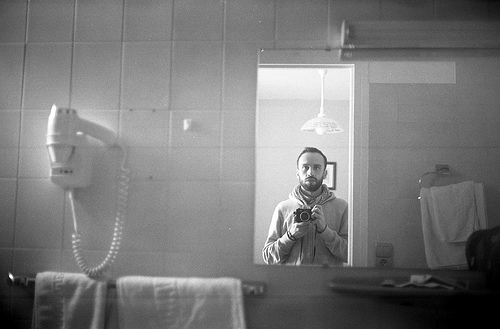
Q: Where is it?
A: This is at the bathroom.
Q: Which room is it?
A: It is a bathroom.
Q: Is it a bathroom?
A: Yes, it is a bathroom.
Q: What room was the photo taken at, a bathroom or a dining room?
A: It was taken at a bathroom.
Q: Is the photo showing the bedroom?
A: No, the picture is showing the bathroom.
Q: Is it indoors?
A: Yes, it is indoors.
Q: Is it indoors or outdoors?
A: It is indoors.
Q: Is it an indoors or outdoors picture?
A: It is indoors.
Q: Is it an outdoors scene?
A: No, it is indoors.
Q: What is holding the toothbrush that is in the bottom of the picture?
A: The bathroom is holding the toothbrush.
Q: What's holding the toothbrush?
A: The bathroom is holding the toothbrush.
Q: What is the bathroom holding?
A: The bathroom is holding the toothbrush.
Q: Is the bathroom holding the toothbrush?
A: Yes, the bathroom is holding the toothbrush.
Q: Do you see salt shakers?
A: No, there are no salt shakers.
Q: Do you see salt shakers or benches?
A: No, there are no salt shakers or benches.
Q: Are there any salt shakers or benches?
A: No, there are no salt shakers or benches.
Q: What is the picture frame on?
A: The picture frame is on the wall.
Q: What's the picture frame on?
A: The picture frame is on the wall.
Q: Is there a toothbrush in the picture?
A: Yes, there is a toothbrush.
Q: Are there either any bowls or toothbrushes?
A: Yes, there is a toothbrush.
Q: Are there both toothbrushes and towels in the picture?
A: Yes, there are both a toothbrush and a towel.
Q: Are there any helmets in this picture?
A: No, there are no helmets.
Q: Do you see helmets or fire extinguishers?
A: No, there are no helmets or fire extinguishers.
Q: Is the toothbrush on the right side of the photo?
A: Yes, the toothbrush is on the right of the image.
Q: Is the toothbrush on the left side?
A: No, the toothbrush is on the right of the image.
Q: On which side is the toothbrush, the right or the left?
A: The toothbrush is on the right of the image.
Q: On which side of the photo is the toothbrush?
A: The toothbrush is on the right of the image.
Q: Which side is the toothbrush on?
A: The toothbrush is on the right of the image.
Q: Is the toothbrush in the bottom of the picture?
A: Yes, the toothbrush is in the bottom of the image.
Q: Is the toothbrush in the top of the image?
A: No, the toothbrush is in the bottom of the image.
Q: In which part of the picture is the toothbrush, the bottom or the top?
A: The toothbrush is in the bottom of the image.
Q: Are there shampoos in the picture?
A: No, there are no shampoos.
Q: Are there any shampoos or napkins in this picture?
A: No, there are no shampoos or napkins.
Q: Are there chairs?
A: No, there are no chairs.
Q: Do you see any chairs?
A: No, there are no chairs.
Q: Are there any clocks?
A: No, there are no clocks.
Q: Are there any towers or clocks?
A: No, there are no clocks or towers.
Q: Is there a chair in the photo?
A: No, there are no chairs.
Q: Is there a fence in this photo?
A: No, there are no fences.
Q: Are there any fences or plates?
A: No, there are no fences or plates.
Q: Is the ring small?
A: Yes, the ring is small.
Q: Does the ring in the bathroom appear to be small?
A: Yes, the ring is small.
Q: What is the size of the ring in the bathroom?
A: The ring is small.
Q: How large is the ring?
A: The ring is small.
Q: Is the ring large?
A: No, the ring is small.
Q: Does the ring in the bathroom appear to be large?
A: No, the ring is small.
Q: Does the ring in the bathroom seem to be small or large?
A: The ring is small.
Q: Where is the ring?
A: The ring is in the bathroom.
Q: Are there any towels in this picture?
A: Yes, there is a towel.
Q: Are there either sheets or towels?
A: Yes, there is a towel.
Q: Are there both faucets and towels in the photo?
A: No, there is a towel but no faucets.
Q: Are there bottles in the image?
A: No, there are no bottles.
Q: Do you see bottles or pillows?
A: No, there are no bottles or pillows.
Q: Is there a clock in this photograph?
A: No, there are no clocks.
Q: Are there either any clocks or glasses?
A: No, there are no clocks or glasses.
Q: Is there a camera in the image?
A: Yes, there is a camera.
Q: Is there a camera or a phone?
A: Yes, there is a camera.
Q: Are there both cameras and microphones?
A: No, there is a camera but no microphones.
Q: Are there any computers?
A: No, there are no computers.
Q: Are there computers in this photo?
A: No, there are no computers.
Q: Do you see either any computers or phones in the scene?
A: No, there are no computers or phones.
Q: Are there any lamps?
A: Yes, there is a lamp.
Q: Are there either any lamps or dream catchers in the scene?
A: Yes, there is a lamp.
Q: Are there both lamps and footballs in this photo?
A: No, there is a lamp but no footballs.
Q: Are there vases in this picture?
A: No, there are no vases.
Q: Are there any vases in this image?
A: No, there are no vases.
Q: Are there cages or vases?
A: No, there are no vases or cages.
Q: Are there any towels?
A: Yes, there is a towel.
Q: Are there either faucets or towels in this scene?
A: Yes, there is a towel.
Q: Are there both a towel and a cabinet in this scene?
A: No, there is a towel but no cabinets.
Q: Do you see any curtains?
A: No, there are no curtains.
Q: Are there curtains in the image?
A: No, there are no curtains.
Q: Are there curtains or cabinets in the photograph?
A: No, there are no curtains or cabinets.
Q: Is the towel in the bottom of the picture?
A: Yes, the towel is in the bottom of the image.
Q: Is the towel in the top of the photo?
A: No, the towel is in the bottom of the image.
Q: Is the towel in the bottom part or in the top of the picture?
A: The towel is in the bottom of the image.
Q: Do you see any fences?
A: No, there are no fences.